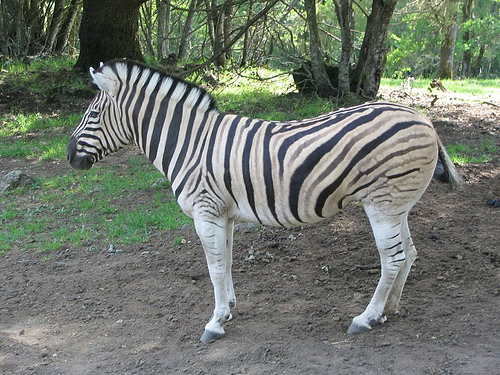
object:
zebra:
[62, 54, 467, 344]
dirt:
[0, 253, 197, 375]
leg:
[194, 216, 231, 345]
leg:
[222, 223, 240, 319]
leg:
[344, 208, 406, 338]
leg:
[388, 218, 420, 314]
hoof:
[200, 327, 225, 346]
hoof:
[345, 318, 369, 336]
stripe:
[236, 122, 332, 222]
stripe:
[164, 91, 203, 188]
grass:
[0, 173, 160, 253]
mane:
[87, 59, 213, 115]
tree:
[346, 0, 402, 99]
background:
[0, 0, 499, 58]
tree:
[68, 0, 149, 75]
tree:
[188, 0, 245, 75]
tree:
[421, 0, 476, 81]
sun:
[224, 63, 300, 91]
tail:
[433, 137, 467, 193]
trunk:
[72, 0, 145, 71]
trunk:
[209, 1, 226, 67]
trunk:
[299, 0, 335, 95]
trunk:
[333, 0, 358, 92]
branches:
[236, 0, 289, 72]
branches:
[161, 0, 204, 70]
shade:
[0, 100, 500, 375]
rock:
[1, 165, 46, 192]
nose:
[64, 142, 98, 175]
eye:
[87, 110, 104, 121]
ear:
[82, 62, 118, 90]